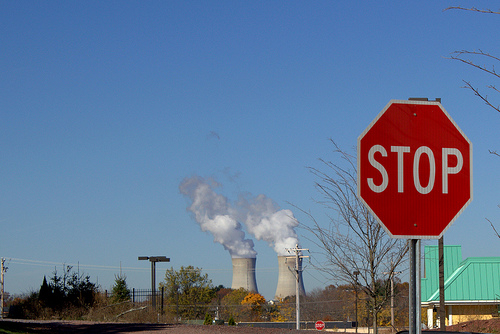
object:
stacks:
[274, 252, 309, 296]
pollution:
[180, 170, 300, 256]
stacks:
[231, 248, 258, 295]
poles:
[148, 261, 157, 324]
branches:
[332, 134, 408, 333]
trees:
[39, 266, 52, 308]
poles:
[292, 256, 303, 328]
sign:
[353, 99, 473, 240]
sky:
[64, 51, 288, 133]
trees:
[240, 291, 265, 314]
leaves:
[245, 294, 255, 301]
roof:
[419, 245, 498, 306]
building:
[414, 242, 497, 329]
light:
[136, 254, 170, 262]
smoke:
[239, 189, 299, 255]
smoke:
[180, 174, 257, 260]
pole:
[407, 238, 422, 332]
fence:
[130, 286, 162, 305]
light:
[139, 252, 170, 308]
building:
[273, 248, 307, 303]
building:
[228, 256, 260, 297]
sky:
[4, 2, 497, 248]